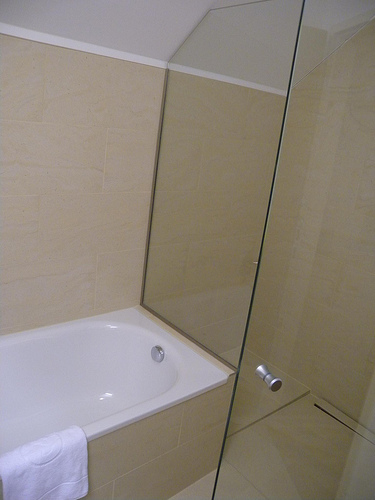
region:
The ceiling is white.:
[87, 8, 139, 33]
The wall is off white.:
[57, 181, 104, 230]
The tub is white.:
[50, 346, 128, 399]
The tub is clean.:
[64, 341, 120, 397]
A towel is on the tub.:
[0, 415, 99, 498]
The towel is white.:
[0, 413, 106, 499]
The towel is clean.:
[1, 390, 95, 497]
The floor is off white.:
[250, 437, 319, 484]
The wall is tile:
[8, 150, 136, 285]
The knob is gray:
[248, 351, 295, 408]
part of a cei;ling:
[134, 24, 164, 49]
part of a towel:
[25, 475, 37, 494]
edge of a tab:
[113, 427, 120, 433]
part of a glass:
[271, 430, 298, 473]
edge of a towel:
[79, 460, 84, 479]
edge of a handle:
[268, 380, 280, 392]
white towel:
[50, 425, 111, 498]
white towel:
[47, 424, 91, 480]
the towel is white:
[21, 428, 81, 470]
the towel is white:
[29, 420, 101, 492]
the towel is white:
[55, 446, 120, 483]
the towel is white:
[15, 423, 56, 483]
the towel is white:
[24, 437, 62, 459]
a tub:
[58, 349, 172, 491]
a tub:
[98, 329, 204, 498]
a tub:
[110, 345, 178, 455]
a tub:
[69, 303, 146, 420]